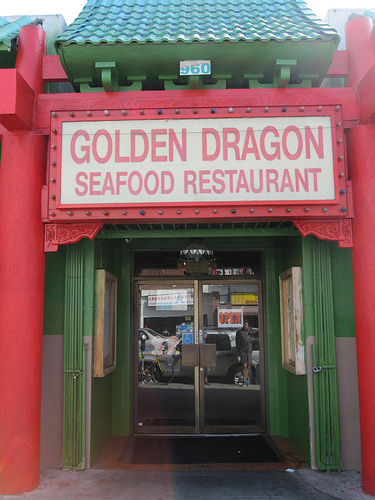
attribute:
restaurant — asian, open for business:
[2, 0, 372, 497]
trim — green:
[114, 241, 282, 438]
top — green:
[55, 0, 340, 82]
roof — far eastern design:
[54, 0, 339, 42]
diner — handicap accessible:
[2, 1, 371, 498]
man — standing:
[230, 319, 258, 390]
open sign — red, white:
[215, 307, 246, 328]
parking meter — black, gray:
[136, 331, 148, 380]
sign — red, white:
[45, 106, 344, 213]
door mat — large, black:
[130, 427, 276, 465]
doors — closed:
[132, 277, 266, 436]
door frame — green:
[114, 247, 289, 442]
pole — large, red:
[4, 130, 51, 498]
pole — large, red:
[341, 121, 374, 496]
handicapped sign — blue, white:
[179, 330, 197, 346]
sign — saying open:
[214, 306, 247, 329]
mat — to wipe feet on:
[135, 432, 275, 466]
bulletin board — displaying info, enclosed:
[93, 263, 120, 379]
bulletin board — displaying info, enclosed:
[274, 264, 308, 377]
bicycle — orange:
[139, 341, 177, 385]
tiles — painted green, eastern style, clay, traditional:
[61, 1, 339, 47]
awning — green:
[51, 0, 342, 80]